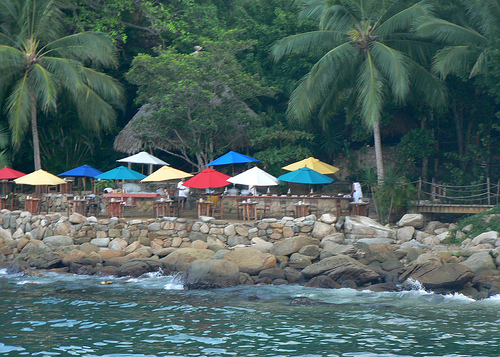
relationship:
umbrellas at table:
[179, 146, 341, 196] [186, 190, 359, 205]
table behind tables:
[186, 190, 359, 205] [33, 190, 348, 210]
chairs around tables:
[25, 193, 267, 223] [33, 190, 348, 210]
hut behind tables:
[325, 131, 415, 196] [33, 190, 348, 210]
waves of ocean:
[44, 262, 183, 297] [4, 269, 499, 354]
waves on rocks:
[44, 262, 183, 297] [6, 231, 491, 298]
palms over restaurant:
[1, 5, 496, 136] [2, 146, 368, 215]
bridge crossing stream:
[401, 177, 495, 214] [441, 221, 460, 224]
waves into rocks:
[44, 262, 183, 297] [6, 231, 491, 298]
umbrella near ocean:
[272, 165, 332, 190] [4, 269, 499, 354]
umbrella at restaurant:
[226, 164, 283, 194] [2, 146, 368, 215]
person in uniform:
[348, 179, 363, 202] [353, 180, 362, 198]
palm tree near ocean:
[1, 1, 127, 172] [4, 269, 499, 354]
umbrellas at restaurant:
[179, 146, 341, 196] [2, 146, 368, 215]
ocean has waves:
[4, 269, 499, 354] [44, 262, 183, 297]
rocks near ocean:
[6, 231, 491, 298] [4, 269, 499, 354]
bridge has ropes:
[401, 177, 495, 214] [422, 179, 485, 197]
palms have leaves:
[1, 5, 496, 136] [43, 22, 124, 130]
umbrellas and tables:
[179, 146, 341, 196] [33, 190, 348, 210]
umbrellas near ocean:
[179, 146, 341, 196] [4, 269, 499, 354]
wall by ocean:
[360, 150, 410, 183] [4, 269, 499, 354]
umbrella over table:
[178, 163, 235, 192] [186, 190, 359, 205]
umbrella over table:
[272, 165, 332, 190] [186, 190, 359, 205]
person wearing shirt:
[175, 178, 191, 204] [171, 182, 191, 195]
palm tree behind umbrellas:
[1, 1, 127, 172] [179, 146, 341, 196]